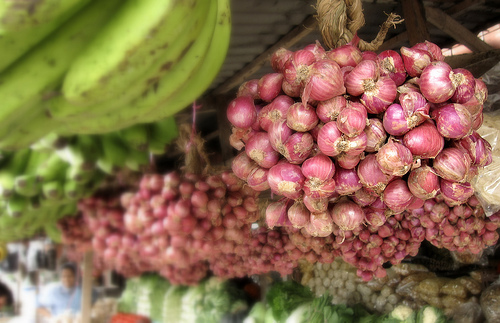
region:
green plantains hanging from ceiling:
[10, 13, 208, 100]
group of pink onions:
[257, 15, 497, 197]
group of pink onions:
[95, 211, 163, 283]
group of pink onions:
[123, 174, 188, 269]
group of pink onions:
[195, 188, 275, 277]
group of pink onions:
[351, 227, 409, 282]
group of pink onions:
[436, 205, 496, 255]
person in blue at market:
[31, 259, 121, 301]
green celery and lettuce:
[99, 269, 246, 321]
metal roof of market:
[240, 9, 270, 95]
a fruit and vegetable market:
[0, 0, 499, 322]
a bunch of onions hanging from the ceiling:
[225, 0, 492, 237]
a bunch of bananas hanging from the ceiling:
[0, 0, 232, 150]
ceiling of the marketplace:
[204, 0, 499, 94]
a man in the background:
[37, 263, 99, 322]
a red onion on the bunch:
[225, 95, 257, 128]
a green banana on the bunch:
[60, 0, 202, 105]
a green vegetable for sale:
[416, 304, 445, 321]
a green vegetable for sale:
[202, 289, 233, 320]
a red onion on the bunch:
[430, 102, 475, 139]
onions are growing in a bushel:
[215, 97, 496, 182]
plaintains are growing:
[56, 29, 291, 174]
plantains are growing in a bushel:
[29, 10, 262, 114]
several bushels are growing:
[29, 197, 494, 284]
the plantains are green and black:
[35, 20, 221, 165]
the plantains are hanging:
[32, 11, 427, 196]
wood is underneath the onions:
[295, 248, 416, 319]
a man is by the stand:
[28, 250, 115, 302]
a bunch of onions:
[212, 20, 497, 238]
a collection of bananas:
[0, 3, 240, 150]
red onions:
[222, 96, 260, 128]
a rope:
[310, 1, 406, 51]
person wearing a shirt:
[29, 257, 94, 322]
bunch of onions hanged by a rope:
[53, 0, 490, 288]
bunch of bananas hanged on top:
[3, 8, 248, 250]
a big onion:
[415, 57, 467, 107]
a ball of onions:
[224, 34, 492, 238]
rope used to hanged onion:
[165, 117, 226, 181]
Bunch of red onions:
[217, 23, 496, 246]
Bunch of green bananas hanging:
[0, 2, 249, 151]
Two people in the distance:
[0, 262, 92, 322]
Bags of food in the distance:
[285, 246, 498, 322]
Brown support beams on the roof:
[391, 0, 497, 94]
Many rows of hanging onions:
[25, 31, 499, 291]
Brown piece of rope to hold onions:
[287, 0, 399, 61]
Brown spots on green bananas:
[75, 26, 201, 116]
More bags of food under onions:
[97, 259, 351, 321]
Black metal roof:
[184, 2, 497, 103]